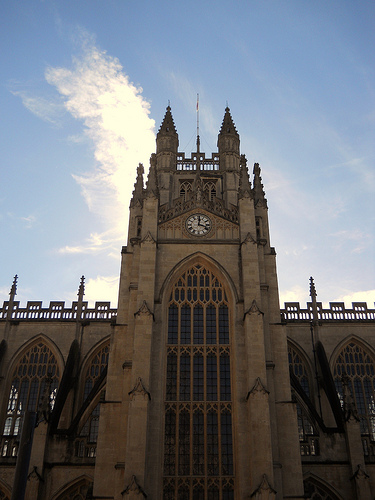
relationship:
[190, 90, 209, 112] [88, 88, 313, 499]
flag on building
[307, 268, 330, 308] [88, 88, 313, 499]
spire on building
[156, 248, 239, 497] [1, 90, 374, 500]
cathedral window in front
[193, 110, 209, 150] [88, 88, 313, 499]
spire on building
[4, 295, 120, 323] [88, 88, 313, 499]
railing on building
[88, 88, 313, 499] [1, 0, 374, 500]
building in city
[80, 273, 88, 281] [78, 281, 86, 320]
cross on pole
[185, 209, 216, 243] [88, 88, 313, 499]
clock on building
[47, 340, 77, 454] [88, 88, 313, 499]
railing on building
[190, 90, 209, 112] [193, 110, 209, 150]
flag on pole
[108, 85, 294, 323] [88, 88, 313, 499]
tower on building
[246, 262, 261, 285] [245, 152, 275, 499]
spot on column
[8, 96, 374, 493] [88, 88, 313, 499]
design on building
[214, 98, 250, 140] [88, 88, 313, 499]
spiral on building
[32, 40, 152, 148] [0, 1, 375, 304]
cloud in sky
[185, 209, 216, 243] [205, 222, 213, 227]
clock has roman numerals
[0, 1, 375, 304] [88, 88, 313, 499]
blue sky over building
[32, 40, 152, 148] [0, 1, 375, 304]
clouds in sky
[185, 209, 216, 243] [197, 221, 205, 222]
clock has hands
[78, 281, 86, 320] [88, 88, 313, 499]
pole on building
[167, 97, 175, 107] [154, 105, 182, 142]
tip of spire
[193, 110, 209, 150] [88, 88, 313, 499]
pole on building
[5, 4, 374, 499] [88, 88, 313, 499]
photograph of church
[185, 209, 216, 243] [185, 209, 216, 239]
clock with clock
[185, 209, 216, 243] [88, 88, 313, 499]
clock on church tower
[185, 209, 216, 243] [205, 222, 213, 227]
clock with roman numerals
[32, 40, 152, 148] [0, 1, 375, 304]
white cloud in sky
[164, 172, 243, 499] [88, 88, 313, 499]
windows on church tower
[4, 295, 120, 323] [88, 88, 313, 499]
fencing on building